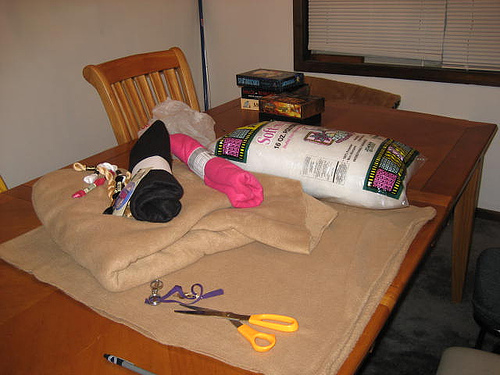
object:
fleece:
[57, 122, 351, 350]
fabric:
[120, 115, 276, 212]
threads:
[56, 148, 136, 230]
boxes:
[242, 71, 305, 135]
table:
[197, 86, 499, 215]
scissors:
[181, 309, 307, 356]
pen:
[97, 342, 137, 373]